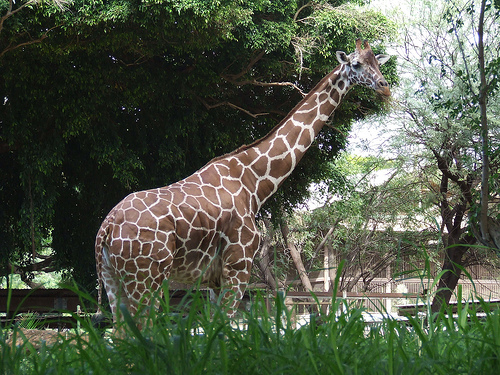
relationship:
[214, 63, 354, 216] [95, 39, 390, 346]
neck on giraffe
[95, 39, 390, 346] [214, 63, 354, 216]
giraffe has neck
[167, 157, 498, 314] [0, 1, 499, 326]
building in background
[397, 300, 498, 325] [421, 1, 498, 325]
bench on other side of tree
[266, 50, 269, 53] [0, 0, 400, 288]
leaf on tree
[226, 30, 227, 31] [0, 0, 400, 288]
leaf on tree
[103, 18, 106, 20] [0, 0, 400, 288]
leaf on tree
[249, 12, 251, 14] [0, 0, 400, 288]
leaf on tree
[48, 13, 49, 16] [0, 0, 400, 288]
leaf on tree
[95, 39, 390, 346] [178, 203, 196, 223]
giraffe has patch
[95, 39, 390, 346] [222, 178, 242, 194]
giraffe has patch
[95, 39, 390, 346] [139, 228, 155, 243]
giraffe has patch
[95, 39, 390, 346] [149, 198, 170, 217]
giraffe has patch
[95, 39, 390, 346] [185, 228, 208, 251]
giraffe has patch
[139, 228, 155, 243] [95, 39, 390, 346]
patch on giraffe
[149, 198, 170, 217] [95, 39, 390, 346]
patch on giraffe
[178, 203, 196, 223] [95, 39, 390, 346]
patch on giraffe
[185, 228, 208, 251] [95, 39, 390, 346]
patch on giraffe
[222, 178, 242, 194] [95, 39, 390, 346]
patch on giraffe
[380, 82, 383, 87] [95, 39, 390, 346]
nostril of giraffe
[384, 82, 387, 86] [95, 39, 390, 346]
nostril of giraffe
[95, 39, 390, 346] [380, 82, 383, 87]
giraffe has nostril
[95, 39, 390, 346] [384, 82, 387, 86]
giraffe has nostril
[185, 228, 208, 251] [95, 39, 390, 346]
spot on giraffe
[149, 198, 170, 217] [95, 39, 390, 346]
spot on giraffe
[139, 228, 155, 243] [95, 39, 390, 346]
spot on giraffe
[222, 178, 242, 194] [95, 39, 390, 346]
spot on giraffe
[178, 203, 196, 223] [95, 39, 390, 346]
spot on giraffe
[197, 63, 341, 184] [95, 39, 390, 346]
mane on giraffe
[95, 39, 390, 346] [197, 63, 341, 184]
giraffe has mane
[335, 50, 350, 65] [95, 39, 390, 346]
ear of giraffe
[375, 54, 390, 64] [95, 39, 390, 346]
ear of giraffe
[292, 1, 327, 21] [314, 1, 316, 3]
branch with leaf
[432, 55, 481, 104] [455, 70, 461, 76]
branch with leaf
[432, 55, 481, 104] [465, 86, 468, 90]
branch with leaf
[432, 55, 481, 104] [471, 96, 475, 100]
branch with leaf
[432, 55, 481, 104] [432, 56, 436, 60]
branch with leaf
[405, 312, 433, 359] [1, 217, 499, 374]
blade of grass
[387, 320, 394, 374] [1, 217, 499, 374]
blade of grass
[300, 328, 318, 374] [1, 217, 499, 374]
blade of grass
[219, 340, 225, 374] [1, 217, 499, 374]
blade of grass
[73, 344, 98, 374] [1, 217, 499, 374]
blade of grass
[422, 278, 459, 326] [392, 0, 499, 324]
trunk of tree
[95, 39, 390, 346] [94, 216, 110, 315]
giraffe has tail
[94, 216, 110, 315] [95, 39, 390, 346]
tail on giraffe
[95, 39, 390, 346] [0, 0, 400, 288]
giraffe in front of tree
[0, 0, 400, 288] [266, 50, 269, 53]
tree has leaf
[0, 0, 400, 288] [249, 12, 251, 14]
tree has leaf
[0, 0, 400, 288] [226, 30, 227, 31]
tree has leaf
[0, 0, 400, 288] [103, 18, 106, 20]
tree has leaf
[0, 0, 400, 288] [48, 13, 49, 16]
tree has leaf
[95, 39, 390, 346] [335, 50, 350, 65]
giraffe has ear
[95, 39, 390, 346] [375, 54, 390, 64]
giraffe has ear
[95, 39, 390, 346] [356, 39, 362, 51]
giraffe has horn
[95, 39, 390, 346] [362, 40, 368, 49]
giraffe has horn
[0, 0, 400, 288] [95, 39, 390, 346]
tree behind giraffe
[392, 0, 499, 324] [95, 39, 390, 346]
tree behind giraffe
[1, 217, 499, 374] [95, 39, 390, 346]
grass in front of giraffe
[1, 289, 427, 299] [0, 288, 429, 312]
railing on fence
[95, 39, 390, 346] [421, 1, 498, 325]
giraffe next to tree